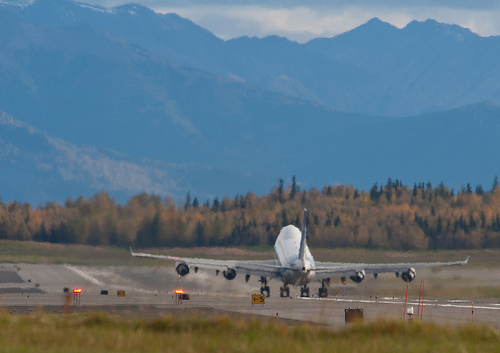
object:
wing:
[129, 245, 282, 280]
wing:
[313, 253, 471, 283]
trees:
[275, 177, 287, 205]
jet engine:
[349, 269, 366, 284]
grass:
[0, 234, 278, 265]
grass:
[308, 245, 500, 270]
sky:
[3, 0, 500, 46]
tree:
[287, 171, 299, 201]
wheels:
[279, 287, 291, 298]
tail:
[248, 206, 361, 276]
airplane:
[127, 207, 472, 298]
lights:
[174, 289, 185, 295]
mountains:
[0, 0, 497, 211]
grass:
[0, 304, 499, 353]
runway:
[0, 262, 500, 330]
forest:
[1, 173, 499, 352]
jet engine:
[222, 264, 237, 281]